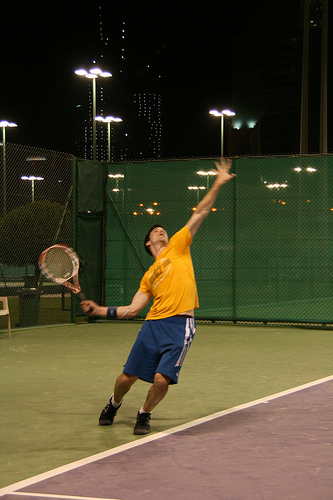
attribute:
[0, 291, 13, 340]
chair — white, plastic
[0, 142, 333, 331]
fence — green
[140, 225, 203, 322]
shirt — yellow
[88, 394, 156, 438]
black sneakers — atheletic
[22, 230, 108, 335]
racket — pink, black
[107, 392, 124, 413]
sock — white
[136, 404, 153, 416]
sock — white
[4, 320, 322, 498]
tennis court — brown, green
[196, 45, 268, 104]
sky — black, night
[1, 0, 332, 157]
sky — night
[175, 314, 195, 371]
stripes — blue, white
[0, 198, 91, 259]
bush — green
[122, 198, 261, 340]
player — yellow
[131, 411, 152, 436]
shoe — black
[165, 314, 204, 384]
stripes — white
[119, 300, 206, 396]
shorts — blue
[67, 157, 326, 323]
fence — green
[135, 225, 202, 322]
t shirt — yellow 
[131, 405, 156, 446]
shoe — on train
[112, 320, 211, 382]
shorts — blue 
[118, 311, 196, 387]
shorts — blue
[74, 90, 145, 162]
light — bright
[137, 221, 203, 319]
shirt — yellow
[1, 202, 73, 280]
tree — small 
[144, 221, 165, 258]
hair — black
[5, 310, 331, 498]
court — green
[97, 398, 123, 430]
shoe — black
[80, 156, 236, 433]
man — playing 